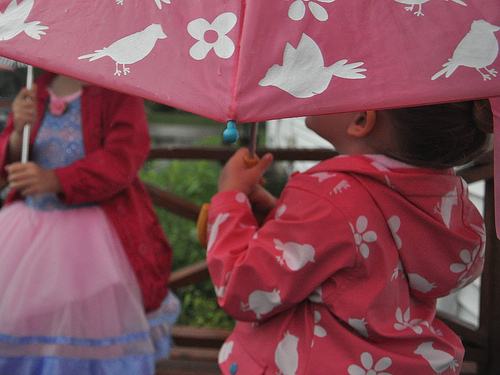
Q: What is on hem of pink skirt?
A: Blue ribbon.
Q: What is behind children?
A: Wood rail.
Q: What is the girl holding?
A: Umbrella.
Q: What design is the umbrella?
A: Bird and flowers.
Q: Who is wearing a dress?
A: Girl on the left.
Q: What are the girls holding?
A: Umbrella.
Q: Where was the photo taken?
A: The yard.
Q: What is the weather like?
A: Over cast.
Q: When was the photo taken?
A: Morning.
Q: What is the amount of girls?
A: Two.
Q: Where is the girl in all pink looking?
A: Up.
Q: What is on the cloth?
A: White flowers.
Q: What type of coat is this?
A: A raincoat.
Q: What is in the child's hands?
A: A handle to umbrella.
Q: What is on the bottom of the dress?
A: Shiny ribbon.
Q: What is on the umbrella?
A: A white bird.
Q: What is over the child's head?
A: A umbrella.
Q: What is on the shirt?
A: A flower.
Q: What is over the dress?
A: A raincoat.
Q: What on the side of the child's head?
A: A ear.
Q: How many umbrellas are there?
A: One.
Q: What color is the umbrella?
A: Pink and white.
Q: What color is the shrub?
A: Green.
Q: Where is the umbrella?
A: Over the front child.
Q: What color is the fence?
A: Brown.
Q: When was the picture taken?
A: Daytime.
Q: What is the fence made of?
A: Wood.